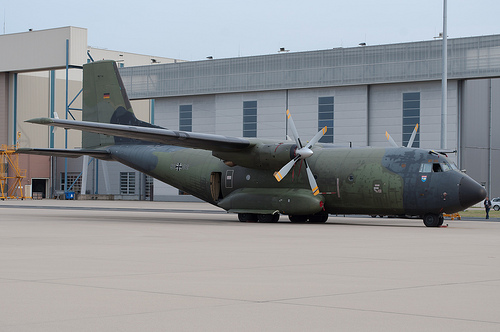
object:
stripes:
[312, 185, 323, 193]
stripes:
[285, 108, 292, 118]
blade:
[303, 156, 320, 197]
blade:
[273, 153, 296, 182]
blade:
[285, 110, 302, 146]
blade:
[303, 125, 330, 148]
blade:
[406, 121, 420, 146]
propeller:
[383, 130, 398, 145]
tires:
[309, 205, 329, 223]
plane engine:
[212, 144, 297, 167]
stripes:
[273, 173, 283, 181]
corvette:
[54, 179, 82, 199]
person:
[482, 196, 492, 219]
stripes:
[384, 131, 393, 140]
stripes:
[322, 123, 330, 133]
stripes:
[311, 185, 319, 196]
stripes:
[275, 171, 282, 183]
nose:
[460, 172, 486, 209]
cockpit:
[419, 160, 446, 172]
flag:
[99, 90, 113, 99]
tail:
[12, 59, 168, 159]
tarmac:
[1, 200, 498, 329]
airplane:
[17, 60, 487, 227]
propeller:
[271, 109, 328, 196]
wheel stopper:
[439, 223, 448, 227]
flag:
[420, 174, 427, 183]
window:
[420, 161, 435, 172]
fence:
[60, 187, 80, 200]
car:
[486, 195, 500, 211]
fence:
[131, 33, 499, 98]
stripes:
[412, 119, 420, 133]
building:
[110, 31, 499, 203]